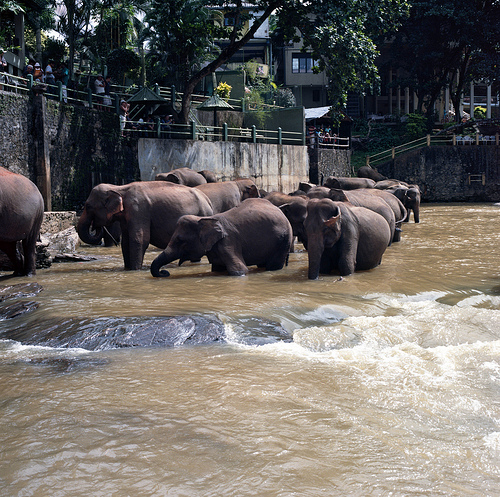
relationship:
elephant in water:
[144, 197, 292, 279] [8, 204, 497, 494]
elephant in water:
[293, 199, 388, 275] [286, 255, 395, 295]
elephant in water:
[73, 180, 207, 264] [83, 245, 167, 292]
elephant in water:
[374, 175, 424, 226] [402, 210, 425, 230]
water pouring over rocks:
[136, 305, 268, 355] [76, 312, 232, 347]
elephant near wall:
[88, 189, 141, 239] [39, 206, 89, 271]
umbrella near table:
[128, 83, 235, 119] [214, 118, 260, 136]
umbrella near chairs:
[128, 83, 235, 119] [167, 115, 191, 130]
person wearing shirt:
[47, 62, 80, 87] [59, 71, 89, 93]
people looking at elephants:
[44, 63, 108, 101] [86, 178, 174, 243]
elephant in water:
[4, 167, 50, 269] [7, 259, 51, 310]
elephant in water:
[194, 172, 264, 215] [203, 276, 289, 318]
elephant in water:
[315, 177, 402, 235] [391, 249, 426, 279]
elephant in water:
[0, 167, 45, 277] [5, 275, 497, 484]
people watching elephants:
[44, 63, 58, 86] [58, 160, 401, 282]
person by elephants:
[311, 122, 341, 147] [89, 150, 338, 277]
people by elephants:
[26, 49, 158, 120] [75, 167, 449, 327]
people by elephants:
[28, 57, 108, 109] [66, 155, 392, 272]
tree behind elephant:
[401, 1, 454, 129] [281, 199, 400, 274]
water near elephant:
[0, 198, 500, 497] [150, 197, 293, 275]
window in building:
[293, 53, 316, 72] [175, 1, 355, 110]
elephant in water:
[150, 197, 293, 275] [8, 204, 497, 494]